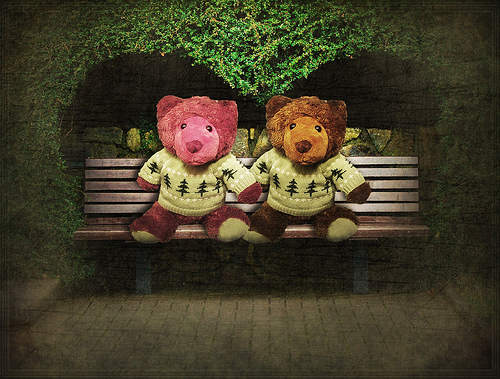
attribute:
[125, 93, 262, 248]
teddy bear — pink, brown, sitting, stuffed, wearing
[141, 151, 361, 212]
shirt — small, white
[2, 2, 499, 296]
bush — heart shapped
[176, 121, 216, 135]
eyes — black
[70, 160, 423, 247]
bench — wooden, armless, silver, red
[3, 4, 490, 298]
wall — flat, stoned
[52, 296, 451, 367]
brick — brown